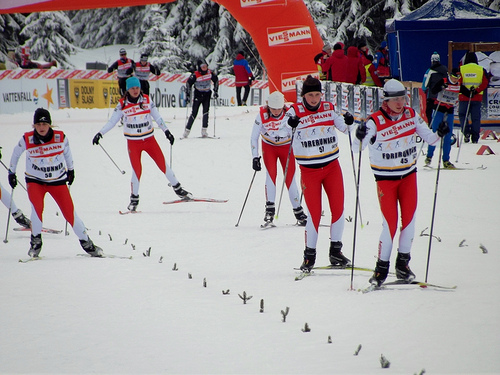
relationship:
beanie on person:
[296, 67, 320, 95] [283, 78, 374, 290]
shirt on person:
[277, 100, 351, 180] [283, 78, 374, 290]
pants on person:
[295, 157, 361, 278] [283, 78, 374, 290]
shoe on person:
[301, 243, 326, 284] [283, 78, 374, 290]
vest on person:
[286, 113, 347, 173] [283, 78, 374, 290]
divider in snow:
[189, 246, 344, 367] [209, 196, 258, 262]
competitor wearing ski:
[107, 70, 208, 230] [194, 189, 231, 214]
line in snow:
[126, 226, 368, 374] [209, 196, 258, 262]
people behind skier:
[62, 33, 485, 288] [181, 44, 222, 148]